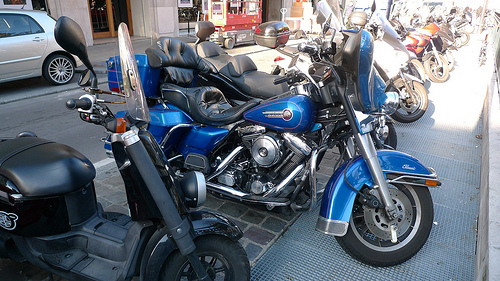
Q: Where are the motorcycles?
A: On the side of the road.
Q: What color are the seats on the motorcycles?
A: Black.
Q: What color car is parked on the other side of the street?
A: Silver.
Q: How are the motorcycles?
A: Parked.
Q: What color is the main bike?
A: Blue.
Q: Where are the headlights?
A: On the front of the motorcycles.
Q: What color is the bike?
A: Blue.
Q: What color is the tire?
A: Black.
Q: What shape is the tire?
A: Round.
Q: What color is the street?
A: Gray.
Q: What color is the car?
A: Silver.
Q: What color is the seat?
A: Black.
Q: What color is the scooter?
A: Black.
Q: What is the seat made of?
A: Leather.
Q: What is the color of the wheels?
A: Black.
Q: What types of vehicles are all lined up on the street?
A: Motorcycles.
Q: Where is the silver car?
A: Across the street.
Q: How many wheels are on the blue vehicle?
A: Two.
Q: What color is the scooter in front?
A: Black.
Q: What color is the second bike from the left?
A: Blue.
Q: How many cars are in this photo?
A: One.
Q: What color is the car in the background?
A: Silver.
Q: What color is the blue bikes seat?
A: Black.